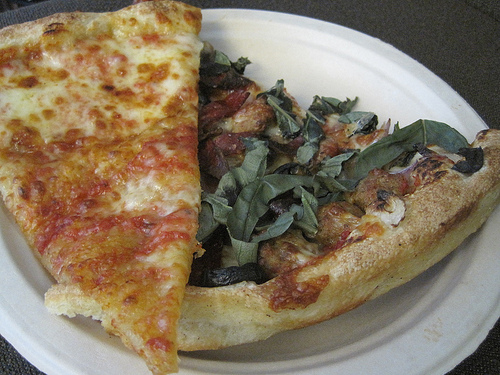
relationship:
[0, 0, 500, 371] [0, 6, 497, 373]
pizza on plate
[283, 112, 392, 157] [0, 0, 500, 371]
bacon on pizza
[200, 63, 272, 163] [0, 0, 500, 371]
bacon on pizza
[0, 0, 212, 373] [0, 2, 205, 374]
cheese on pizza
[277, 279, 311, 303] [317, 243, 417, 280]
spot on crust.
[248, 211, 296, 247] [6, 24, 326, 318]
leaf on top of pizza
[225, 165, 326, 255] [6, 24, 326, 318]
leaf on top of pizza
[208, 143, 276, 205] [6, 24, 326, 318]
leaf on top of pizza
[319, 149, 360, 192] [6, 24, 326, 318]
leaf on top of pizza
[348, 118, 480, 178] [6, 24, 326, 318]
leaf on top of pizza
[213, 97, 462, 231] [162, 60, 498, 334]
herbs are on top of pizza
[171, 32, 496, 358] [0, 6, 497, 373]
slice on top of plate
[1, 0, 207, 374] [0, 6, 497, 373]
slice on top of plate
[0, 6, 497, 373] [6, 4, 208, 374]
plate under pizza slice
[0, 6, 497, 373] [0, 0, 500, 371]
plate under pizza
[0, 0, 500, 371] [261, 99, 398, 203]
pizza has toppings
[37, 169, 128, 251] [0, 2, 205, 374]
sauce on top of pizza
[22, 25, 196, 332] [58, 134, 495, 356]
pizza has crust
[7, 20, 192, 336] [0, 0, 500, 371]
cheese melted in pizza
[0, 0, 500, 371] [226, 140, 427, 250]
pizza has greens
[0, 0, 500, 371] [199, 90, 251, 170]
pizza has meat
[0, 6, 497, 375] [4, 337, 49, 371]
plate with flat edge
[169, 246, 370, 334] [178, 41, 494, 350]
crust of pizza